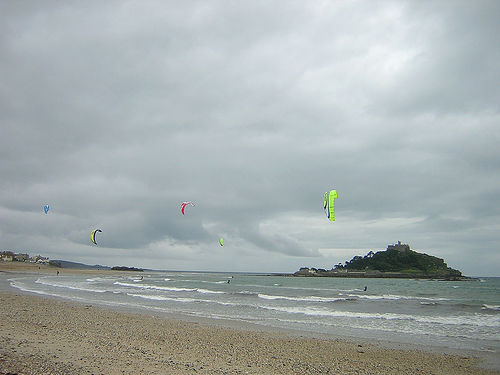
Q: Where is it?
A: This is at the beach.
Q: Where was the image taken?
A: It was taken at the beach.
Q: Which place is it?
A: It is a beach.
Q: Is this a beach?
A: Yes, it is a beach.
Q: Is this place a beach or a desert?
A: It is a beach.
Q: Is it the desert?
A: No, it is the beach.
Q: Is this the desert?
A: No, it is the beach.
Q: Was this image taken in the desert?
A: No, the picture was taken in the beach.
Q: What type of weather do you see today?
A: It is cloudy.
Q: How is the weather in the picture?
A: It is cloudy.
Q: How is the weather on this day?
A: It is cloudy.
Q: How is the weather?
A: It is cloudy.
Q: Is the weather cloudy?
A: Yes, it is cloudy.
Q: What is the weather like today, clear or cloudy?
A: It is cloudy.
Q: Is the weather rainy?
A: No, it is cloudy.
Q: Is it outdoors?
A: Yes, it is outdoors.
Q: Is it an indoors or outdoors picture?
A: It is outdoors.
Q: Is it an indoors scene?
A: No, it is outdoors.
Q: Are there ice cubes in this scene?
A: No, there are no ice cubes.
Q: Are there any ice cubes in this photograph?
A: No, there are no ice cubes.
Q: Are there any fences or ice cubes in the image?
A: No, there are no ice cubes or fences.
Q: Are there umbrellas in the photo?
A: No, there are no umbrellas.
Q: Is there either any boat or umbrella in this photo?
A: No, there are no umbrellas or boats.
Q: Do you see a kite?
A: Yes, there is a kite.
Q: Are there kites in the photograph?
A: Yes, there is a kite.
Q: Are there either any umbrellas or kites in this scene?
A: Yes, there is a kite.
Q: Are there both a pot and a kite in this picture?
A: No, there is a kite but no pots.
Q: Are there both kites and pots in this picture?
A: No, there is a kite but no pots.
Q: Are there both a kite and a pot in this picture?
A: No, there is a kite but no pots.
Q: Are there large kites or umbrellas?
A: Yes, there is a large kite.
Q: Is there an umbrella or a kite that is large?
A: Yes, the kite is large.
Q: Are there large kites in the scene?
A: Yes, there is a large kite.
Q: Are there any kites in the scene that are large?
A: Yes, there is a kite that is large.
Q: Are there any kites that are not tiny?
A: Yes, there is a large kite.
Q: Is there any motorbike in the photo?
A: No, there are no motorcycles.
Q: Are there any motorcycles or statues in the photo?
A: No, there are no motorcycles or statues.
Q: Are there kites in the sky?
A: Yes, there is a kite in the sky.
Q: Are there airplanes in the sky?
A: No, there is a kite in the sky.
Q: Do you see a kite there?
A: Yes, there is a kite.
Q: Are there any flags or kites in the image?
A: Yes, there is a kite.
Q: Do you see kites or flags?
A: Yes, there is a kite.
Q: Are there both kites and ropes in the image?
A: No, there is a kite but no ropes.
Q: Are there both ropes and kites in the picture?
A: No, there is a kite but no ropes.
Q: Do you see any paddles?
A: No, there are no paddles.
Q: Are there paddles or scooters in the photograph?
A: No, there are no paddles or scooters.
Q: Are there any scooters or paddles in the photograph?
A: No, there are no paddles or scooters.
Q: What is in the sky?
A: The kite is in the sky.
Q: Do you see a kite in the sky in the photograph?
A: Yes, there is a kite in the sky.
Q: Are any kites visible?
A: Yes, there is a kite.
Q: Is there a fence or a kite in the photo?
A: Yes, there is a kite.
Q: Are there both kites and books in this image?
A: No, there is a kite but no books.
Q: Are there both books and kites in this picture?
A: No, there is a kite but no books.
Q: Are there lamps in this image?
A: No, there are no lamps.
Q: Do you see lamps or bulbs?
A: No, there are no lamps or bulbs.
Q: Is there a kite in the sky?
A: Yes, there is a kite in the sky.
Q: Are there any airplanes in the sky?
A: No, there is a kite in the sky.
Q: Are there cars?
A: No, there are no cars.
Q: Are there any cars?
A: No, there are no cars.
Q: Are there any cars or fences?
A: No, there are no cars or fences.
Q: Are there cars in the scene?
A: No, there are no cars.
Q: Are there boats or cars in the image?
A: No, there are no cars or boats.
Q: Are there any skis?
A: No, there are no skis.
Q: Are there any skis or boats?
A: No, there are no skis or boats.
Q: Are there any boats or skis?
A: No, there are no skis or boats.